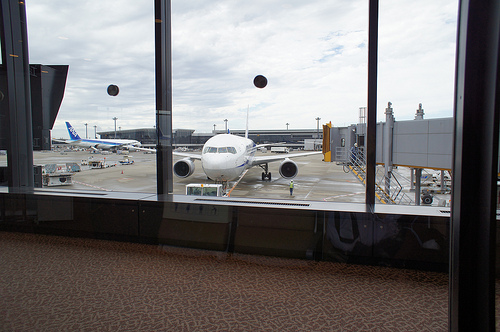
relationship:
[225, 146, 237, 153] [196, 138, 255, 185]
window for plane cockpit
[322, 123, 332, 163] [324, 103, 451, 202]
trim on gate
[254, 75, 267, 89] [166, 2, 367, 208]
magnet on window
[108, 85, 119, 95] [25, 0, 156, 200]
magnet on airport window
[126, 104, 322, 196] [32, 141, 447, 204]
airplane on ground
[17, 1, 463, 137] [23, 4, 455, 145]
clouds in sky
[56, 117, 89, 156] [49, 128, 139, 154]
tail of airplane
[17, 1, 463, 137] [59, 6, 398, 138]
clouds in sky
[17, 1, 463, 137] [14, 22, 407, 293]
clouds over airport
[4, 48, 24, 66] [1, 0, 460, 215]
light reflected in windows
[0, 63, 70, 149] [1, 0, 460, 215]
light reflected in windows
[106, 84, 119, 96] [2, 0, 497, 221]
magnet on window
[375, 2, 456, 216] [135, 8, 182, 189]
window partitioned with metal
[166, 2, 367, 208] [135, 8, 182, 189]
window partitioned with metal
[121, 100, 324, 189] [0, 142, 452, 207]
plane atop tarmac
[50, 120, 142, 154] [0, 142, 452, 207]
plane atop tarmac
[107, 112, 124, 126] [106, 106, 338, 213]
light beyond plane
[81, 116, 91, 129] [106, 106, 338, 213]
light beyond plane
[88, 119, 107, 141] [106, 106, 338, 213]
light beyond plane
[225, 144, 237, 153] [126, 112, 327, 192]
window of airplane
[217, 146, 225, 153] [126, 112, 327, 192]
window of airplane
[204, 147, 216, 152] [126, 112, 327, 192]
window of airplane